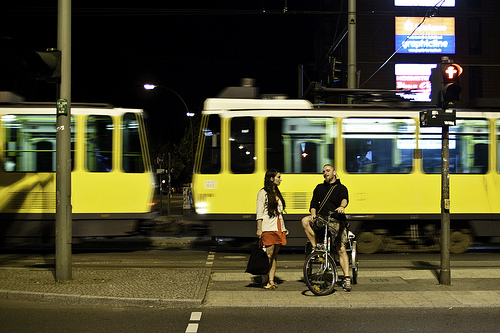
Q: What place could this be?
A: It is a street.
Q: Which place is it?
A: It is a street.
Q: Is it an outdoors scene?
A: Yes, it is outdoors.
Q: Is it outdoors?
A: Yes, it is outdoors.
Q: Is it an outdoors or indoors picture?
A: It is outdoors.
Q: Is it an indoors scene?
A: No, it is outdoors.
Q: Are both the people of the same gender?
A: No, they are both male and female.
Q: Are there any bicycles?
A: Yes, there is a bicycle.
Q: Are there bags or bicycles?
A: Yes, there is a bicycle.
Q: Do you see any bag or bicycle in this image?
A: Yes, there is a bicycle.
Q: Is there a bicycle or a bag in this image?
A: Yes, there is a bicycle.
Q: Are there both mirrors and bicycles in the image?
A: No, there is a bicycle but no mirrors.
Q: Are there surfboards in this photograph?
A: No, there are no surfboards.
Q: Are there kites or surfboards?
A: No, there are no surfboards or kites.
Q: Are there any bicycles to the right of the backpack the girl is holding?
A: Yes, there is a bicycle to the right of the backpack.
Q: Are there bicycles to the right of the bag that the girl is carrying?
A: Yes, there is a bicycle to the right of the backpack.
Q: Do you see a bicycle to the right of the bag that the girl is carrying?
A: Yes, there is a bicycle to the right of the backpack.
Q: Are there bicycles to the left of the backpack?
A: No, the bicycle is to the right of the backpack.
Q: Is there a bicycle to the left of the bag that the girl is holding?
A: No, the bicycle is to the right of the backpack.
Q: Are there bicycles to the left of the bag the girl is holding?
A: No, the bicycle is to the right of the backpack.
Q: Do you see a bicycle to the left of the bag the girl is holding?
A: No, the bicycle is to the right of the backpack.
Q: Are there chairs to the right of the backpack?
A: No, there is a bicycle to the right of the backpack.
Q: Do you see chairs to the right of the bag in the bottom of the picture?
A: No, there is a bicycle to the right of the backpack.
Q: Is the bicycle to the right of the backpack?
A: Yes, the bicycle is to the right of the backpack.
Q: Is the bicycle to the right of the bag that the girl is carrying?
A: Yes, the bicycle is to the right of the backpack.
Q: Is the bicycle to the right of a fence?
A: No, the bicycle is to the right of the backpack.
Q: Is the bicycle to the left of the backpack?
A: No, the bicycle is to the right of the backpack.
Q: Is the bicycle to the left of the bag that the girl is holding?
A: No, the bicycle is to the right of the backpack.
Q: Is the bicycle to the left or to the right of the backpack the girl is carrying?
A: The bicycle is to the right of the backpack.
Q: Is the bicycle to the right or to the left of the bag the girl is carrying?
A: The bicycle is to the right of the backpack.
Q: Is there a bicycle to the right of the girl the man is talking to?
A: Yes, there is a bicycle to the right of the girl.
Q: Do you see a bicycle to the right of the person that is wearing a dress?
A: Yes, there is a bicycle to the right of the girl.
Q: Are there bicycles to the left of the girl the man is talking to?
A: No, the bicycle is to the right of the girl.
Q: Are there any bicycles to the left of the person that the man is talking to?
A: No, the bicycle is to the right of the girl.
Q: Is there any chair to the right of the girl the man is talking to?
A: No, there is a bicycle to the right of the girl.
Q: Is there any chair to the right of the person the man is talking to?
A: No, there is a bicycle to the right of the girl.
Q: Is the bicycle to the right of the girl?
A: Yes, the bicycle is to the right of the girl.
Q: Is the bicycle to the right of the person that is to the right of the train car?
A: Yes, the bicycle is to the right of the girl.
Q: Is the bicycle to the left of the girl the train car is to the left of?
A: No, the bicycle is to the right of the girl.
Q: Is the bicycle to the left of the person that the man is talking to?
A: No, the bicycle is to the right of the girl.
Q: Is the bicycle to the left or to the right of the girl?
A: The bicycle is to the right of the girl.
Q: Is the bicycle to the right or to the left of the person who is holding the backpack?
A: The bicycle is to the right of the girl.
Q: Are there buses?
A: Yes, there is a bus.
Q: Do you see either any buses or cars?
A: Yes, there is a bus.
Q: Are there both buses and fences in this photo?
A: No, there is a bus but no fences.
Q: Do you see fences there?
A: No, there are no fences.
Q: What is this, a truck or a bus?
A: This is a bus.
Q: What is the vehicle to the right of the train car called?
A: The vehicle is a bus.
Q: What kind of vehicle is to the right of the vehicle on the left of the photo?
A: The vehicle is a bus.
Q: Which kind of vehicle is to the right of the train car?
A: The vehicle is a bus.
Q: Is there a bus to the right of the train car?
A: Yes, there is a bus to the right of the train car.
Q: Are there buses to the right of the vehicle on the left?
A: Yes, there is a bus to the right of the train car.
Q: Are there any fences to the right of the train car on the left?
A: No, there is a bus to the right of the train car.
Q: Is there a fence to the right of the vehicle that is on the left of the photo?
A: No, there is a bus to the right of the train car.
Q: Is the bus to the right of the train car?
A: Yes, the bus is to the right of the train car.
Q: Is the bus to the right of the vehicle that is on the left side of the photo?
A: Yes, the bus is to the right of the train car.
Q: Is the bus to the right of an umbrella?
A: No, the bus is to the right of the train car.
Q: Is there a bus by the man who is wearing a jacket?
A: Yes, there is a bus by the man.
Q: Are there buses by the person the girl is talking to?
A: Yes, there is a bus by the man.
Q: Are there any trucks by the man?
A: No, there is a bus by the man.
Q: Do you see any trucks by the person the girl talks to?
A: No, there is a bus by the man.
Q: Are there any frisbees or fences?
A: No, there are no fences or frisbees.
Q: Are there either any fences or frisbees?
A: No, there are no fences or frisbees.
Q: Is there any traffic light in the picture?
A: Yes, there is a traffic light.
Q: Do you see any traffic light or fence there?
A: Yes, there is a traffic light.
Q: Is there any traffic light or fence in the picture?
A: Yes, there is a traffic light.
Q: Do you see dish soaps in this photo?
A: No, there are no dish soaps.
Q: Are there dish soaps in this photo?
A: No, there are no dish soaps.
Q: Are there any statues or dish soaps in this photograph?
A: No, there are no dish soaps or statues.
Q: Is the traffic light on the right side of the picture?
A: Yes, the traffic light is on the right of the image.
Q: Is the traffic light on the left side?
A: No, the traffic light is on the right of the image.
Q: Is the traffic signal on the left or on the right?
A: The traffic signal is on the right of the image.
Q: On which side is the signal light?
A: The signal light is on the right of the image.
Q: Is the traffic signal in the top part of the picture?
A: Yes, the traffic signal is in the top of the image.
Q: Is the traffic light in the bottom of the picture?
A: No, the traffic light is in the top of the image.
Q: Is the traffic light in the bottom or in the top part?
A: The traffic light is in the top of the image.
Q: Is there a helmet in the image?
A: No, there are no helmets.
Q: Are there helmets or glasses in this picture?
A: No, there are no helmets or glasses.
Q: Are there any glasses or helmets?
A: No, there are no helmets or glasses.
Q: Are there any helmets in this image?
A: No, there are no helmets.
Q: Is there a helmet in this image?
A: No, there are no helmets.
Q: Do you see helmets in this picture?
A: No, there are no helmets.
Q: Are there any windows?
A: Yes, there is a window.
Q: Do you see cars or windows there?
A: Yes, there is a window.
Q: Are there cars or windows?
A: Yes, there is a window.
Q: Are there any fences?
A: No, there are no fences.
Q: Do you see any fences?
A: No, there are no fences.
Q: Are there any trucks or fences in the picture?
A: No, there are no fences or trucks.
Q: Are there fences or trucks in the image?
A: No, there are no fences or trucks.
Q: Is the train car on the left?
A: Yes, the train car is on the left of the image.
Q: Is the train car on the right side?
A: No, the train car is on the left of the image.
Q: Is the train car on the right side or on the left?
A: The train car is on the left of the image.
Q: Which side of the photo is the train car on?
A: The train car is on the left of the image.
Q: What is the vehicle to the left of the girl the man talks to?
A: The vehicle is a train car.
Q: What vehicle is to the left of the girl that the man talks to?
A: The vehicle is a train car.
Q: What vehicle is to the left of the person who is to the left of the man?
A: The vehicle is a train car.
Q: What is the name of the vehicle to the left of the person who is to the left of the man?
A: The vehicle is a train car.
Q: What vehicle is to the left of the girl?
A: The vehicle is a train car.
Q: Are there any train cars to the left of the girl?
A: Yes, there is a train car to the left of the girl.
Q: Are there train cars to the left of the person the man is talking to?
A: Yes, there is a train car to the left of the girl.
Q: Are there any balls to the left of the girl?
A: No, there is a train car to the left of the girl.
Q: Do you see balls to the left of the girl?
A: No, there is a train car to the left of the girl.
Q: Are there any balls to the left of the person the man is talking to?
A: No, there is a train car to the left of the girl.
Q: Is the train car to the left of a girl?
A: Yes, the train car is to the left of a girl.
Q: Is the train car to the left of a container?
A: No, the train car is to the left of a girl.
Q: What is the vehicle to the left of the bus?
A: The vehicle is a train car.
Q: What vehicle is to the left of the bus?
A: The vehicle is a train car.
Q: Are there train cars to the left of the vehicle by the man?
A: Yes, there is a train car to the left of the bus.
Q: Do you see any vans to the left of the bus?
A: No, there is a train car to the left of the bus.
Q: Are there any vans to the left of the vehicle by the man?
A: No, there is a train car to the left of the bus.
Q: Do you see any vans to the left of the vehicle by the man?
A: No, there is a train car to the left of the bus.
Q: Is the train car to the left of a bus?
A: Yes, the train car is to the left of a bus.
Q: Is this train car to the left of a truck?
A: No, the train car is to the left of a bus.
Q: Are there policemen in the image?
A: No, there are no policemen.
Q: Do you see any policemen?
A: No, there are no policemen.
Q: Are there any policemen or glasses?
A: No, there are no policemen or glasses.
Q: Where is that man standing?
A: The man is standing in the street.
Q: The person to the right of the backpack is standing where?
A: The man is standing in the street.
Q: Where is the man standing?
A: The man is standing in the street.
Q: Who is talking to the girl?
A: The man is talking to the girl.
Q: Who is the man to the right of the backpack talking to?
A: The man is talking to a girl.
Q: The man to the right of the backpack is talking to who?
A: The man is talking to a girl.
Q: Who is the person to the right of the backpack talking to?
A: The man is talking to a girl.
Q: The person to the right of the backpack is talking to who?
A: The man is talking to a girl.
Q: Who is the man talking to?
A: The man is talking to a girl.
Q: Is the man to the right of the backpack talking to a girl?
A: Yes, the man is talking to a girl.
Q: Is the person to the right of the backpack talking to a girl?
A: Yes, the man is talking to a girl.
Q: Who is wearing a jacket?
A: The man is wearing a jacket.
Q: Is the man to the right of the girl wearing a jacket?
A: Yes, the man is wearing a jacket.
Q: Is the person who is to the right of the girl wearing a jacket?
A: Yes, the man is wearing a jacket.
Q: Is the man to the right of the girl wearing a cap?
A: No, the man is wearing a jacket.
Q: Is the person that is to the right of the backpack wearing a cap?
A: No, the man is wearing a jacket.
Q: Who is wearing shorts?
A: The man is wearing shorts.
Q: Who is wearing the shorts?
A: The man is wearing shorts.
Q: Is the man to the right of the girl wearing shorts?
A: Yes, the man is wearing shorts.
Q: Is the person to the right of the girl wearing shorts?
A: Yes, the man is wearing shorts.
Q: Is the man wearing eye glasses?
A: No, the man is wearing shorts.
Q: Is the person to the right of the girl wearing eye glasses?
A: No, the man is wearing shorts.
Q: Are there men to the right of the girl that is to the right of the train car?
A: Yes, there is a man to the right of the girl.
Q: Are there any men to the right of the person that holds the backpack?
A: Yes, there is a man to the right of the girl.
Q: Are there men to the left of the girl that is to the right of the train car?
A: No, the man is to the right of the girl.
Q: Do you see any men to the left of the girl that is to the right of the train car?
A: No, the man is to the right of the girl.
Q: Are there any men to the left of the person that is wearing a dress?
A: No, the man is to the right of the girl.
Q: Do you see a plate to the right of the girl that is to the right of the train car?
A: No, there is a man to the right of the girl.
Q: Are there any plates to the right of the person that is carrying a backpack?
A: No, there is a man to the right of the girl.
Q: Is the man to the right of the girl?
A: Yes, the man is to the right of the girl.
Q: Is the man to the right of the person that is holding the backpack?
A: Yes, the man is to the right of the girl.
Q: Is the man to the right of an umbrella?
A: No, the man is to the right of the girl.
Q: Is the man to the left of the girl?
A: No, the man is to the right of the girl.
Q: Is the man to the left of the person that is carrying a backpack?
A: No, the man is to the right of the girl.